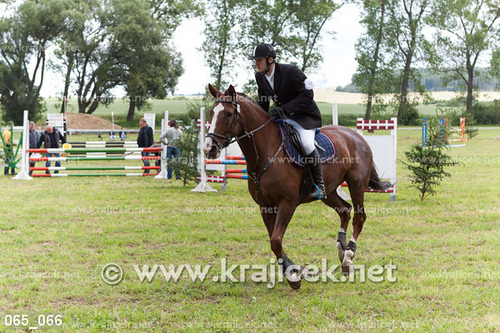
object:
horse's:
[198, 80, 396, 295]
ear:
[224, 83, 236, 96]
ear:
[207, 83, 223, 97]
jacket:
[135, 124, 156, 150]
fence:
[12, 107, 215, 179]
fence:
[335, 99, 401, 172]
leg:
[325, 187, 352, 263]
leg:
[340, 179, 367, 271]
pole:
[29, 147, 162, 155]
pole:
[29, 155, 161, 161]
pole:
[28, 163, 158, 172]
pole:
[30, 170, 159, 177]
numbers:
[0, 311, 20, 331]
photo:
[0, 0, 499, 332]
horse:
[170, 82, 415, 289]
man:
[134, 118, 162, 178]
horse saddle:
[267, 108, 337, 168]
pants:
[278, 117, 321, 156]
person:
[158, 118, 182, 173]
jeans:
[163, 146, 181, 176]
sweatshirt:
[157, 126, 182, 148]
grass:
[1, 127, 498, 331]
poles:
[28, 145, 165, 155]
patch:
[301, 77, 315, 92]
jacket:
[254, 61, 324, 131]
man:
[251, 43, 327, 200]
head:
[200, 81, 247, 163]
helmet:
[248, 45, 277, 58]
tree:
[396, 119, 463, 204]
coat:
[37, 125, 65, 148]